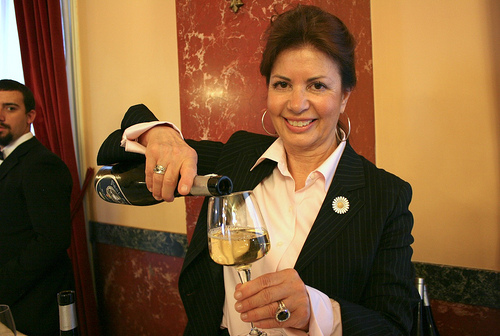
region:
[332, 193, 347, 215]
White daisy pin with yellow center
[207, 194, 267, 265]
Partially filled glass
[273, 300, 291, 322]
Gold ring with blue stone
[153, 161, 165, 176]
Set of silver bands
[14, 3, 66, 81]
Red pleated window curtain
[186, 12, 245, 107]
Red marble design on wall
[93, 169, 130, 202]
Round label on glass bottle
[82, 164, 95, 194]
Red curtain tie back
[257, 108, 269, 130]
Silver hoop earing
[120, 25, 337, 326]
Woman pouring beverage into glass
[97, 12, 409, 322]
a woman pouring wine into a glass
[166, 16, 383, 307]
a woman holding a wine glass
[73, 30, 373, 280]
a woman holding a wine bottle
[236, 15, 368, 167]
a woman wearing ear rings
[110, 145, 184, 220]
a woman wearing a ring on her finger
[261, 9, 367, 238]
a woman wearing a black jacket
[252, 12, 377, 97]
a woman with brown hair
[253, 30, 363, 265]
a woman wearing a white shirt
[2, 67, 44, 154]
a man with short hair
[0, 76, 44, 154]
a man with a beard and mustache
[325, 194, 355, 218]
white pin on coat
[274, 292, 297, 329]
silver and black ring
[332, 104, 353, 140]
large gold hoop earring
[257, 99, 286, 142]
large gold hoop earring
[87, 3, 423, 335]
woman with black hair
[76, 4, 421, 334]
woman pouring some champagne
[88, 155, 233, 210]
black bottle of champagne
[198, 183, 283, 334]
wine glass filled with liquid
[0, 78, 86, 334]
person in a black suit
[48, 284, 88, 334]
top of a champagne bottle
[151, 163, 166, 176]
Ring on a woman's ring finger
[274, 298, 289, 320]
Large black ring worn by a woman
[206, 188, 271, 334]
Wineglass full of wine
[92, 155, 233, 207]
Opened wine bottle for serving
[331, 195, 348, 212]
Flower jewelry pinned to a lapel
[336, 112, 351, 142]
Large hoop earrings worn by a woman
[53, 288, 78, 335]
Top of a wine bottle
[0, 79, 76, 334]
Man watching woman pour a glass of wine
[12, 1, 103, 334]
Scarlet curtains hung in a window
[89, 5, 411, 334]
Woman pouring a glass of wine without watching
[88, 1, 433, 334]
A lady pouring wine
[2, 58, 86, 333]
A man standing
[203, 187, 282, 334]
A glass of wine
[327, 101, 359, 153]
Silver hoop earring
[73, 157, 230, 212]
Wine bottle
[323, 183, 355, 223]
A white daisy pin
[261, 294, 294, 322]
A silver ring with a black stone in the middle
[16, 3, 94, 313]
Red curtains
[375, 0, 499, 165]
Cream colored wall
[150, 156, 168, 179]
Silver ring that the woman is wearing